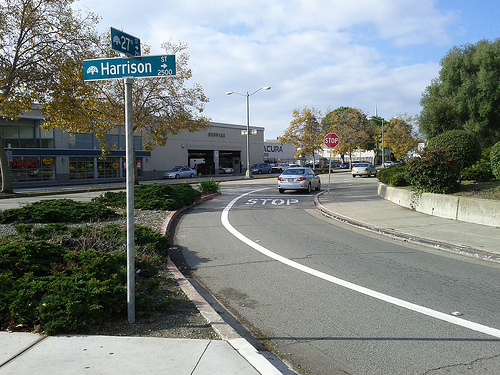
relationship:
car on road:
[277, 166, 322, 194] [160, 174, 497, 366]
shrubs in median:
[0, 179, 222, 329] [1, 181, 285, 373]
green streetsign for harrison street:
[82, 54, 176, 82] [99, 51, 172, 76]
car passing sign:
[270, 161, 337, 208] [80, 48, 180, 93]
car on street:
[162, 162, 198, 182] [0, 162, 499, 373]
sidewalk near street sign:
[0, 331, 270, 373] [78, 52, 178, 77]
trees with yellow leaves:
[276, 102, 416, 177] [299, 123, 367, 128]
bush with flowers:
[402, 142, 460, 192] [421, 149, 431, 156]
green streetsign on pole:
[82, 54, 176, 82] [123, 76, 137, 323]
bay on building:
[187, 148, 215, 175] [0, 97, 265, 192]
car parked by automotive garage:
[162, 165, 197, 179] [141, 114, 265, 177]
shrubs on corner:
[0, 182, 204, 337] [9, 176, 250, 372]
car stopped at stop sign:
[277, 166, 322, 194] [320, 126, 341, 195]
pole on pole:
[123, 77, 136, 323] [123, 77, 136, 323]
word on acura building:
[260, 143, 286, 154] [264, 142, 296, 163]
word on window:
[9, 160, 49, 170] [7, 157, 53, 182]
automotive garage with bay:
[139, 112, 264, 177] [217, 147, 244, 177]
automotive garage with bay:
[139, 112, 264, 177] [188, 146, 216, 176]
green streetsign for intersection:
[82, 54, 176, 82] [195, 176, 376, 194]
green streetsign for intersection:
[110, 26, 142, 57] [195, 176, 376, 194]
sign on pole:
[323, 132, 340, 148] [321, 147, 340, 194]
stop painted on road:
[244, 195, 298, 205] [157, 184, 498, 355]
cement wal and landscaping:
[371, 168, 498, 226] [376, 37, 498, 197]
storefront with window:
[1, 109, 149, 188] [13, 119, 146, 186]